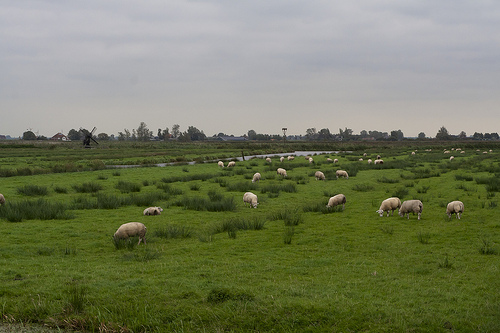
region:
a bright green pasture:
[3, 145, 496, 327]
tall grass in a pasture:
[177, 192, 233, 212]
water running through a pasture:
[101, 144, 358, 173]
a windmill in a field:
[79, 126, 99, 147]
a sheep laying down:
[142, 205, 167, 216]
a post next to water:
[237, 146, 250, 165]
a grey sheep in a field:
[395, 198, 422, 215]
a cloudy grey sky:
[6, 5, 488, 135]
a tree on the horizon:
[436, 126, 448, 138]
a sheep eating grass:
[241, 190, 265, 215]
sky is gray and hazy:
[0, 2, 498, 139]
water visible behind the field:
[108, 147, 340, 165]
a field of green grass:
[1, 145, 498, 331]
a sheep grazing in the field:
[113, 220, 148, 247]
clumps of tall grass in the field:
[211, 216, 266, 236]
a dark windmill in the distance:
[79, 127, 99, 149]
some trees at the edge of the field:
[436, 125, 451, 140]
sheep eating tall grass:
[324, 192, 346, 209]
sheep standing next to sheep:
[376, 195, 401, 218]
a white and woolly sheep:
[240, 191, 260, 210]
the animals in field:
[321, 176, 473, 301]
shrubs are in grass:
[156, 210, 311, 260]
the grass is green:
[225, 240, 462, 319]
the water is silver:
[282, 147, 322, 154]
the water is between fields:
[256, 144, 343, 173]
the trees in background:
[32, 124, 285, 144]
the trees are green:
[66, 122, 219, 139]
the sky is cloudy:
[29, 22, 444, 110]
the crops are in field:
[31, 142, 163, 172]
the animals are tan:
[317, 176, 472, 241]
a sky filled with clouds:
[2, 1, 496, 111]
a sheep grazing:
[102, 214, 160, 249]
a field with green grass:
[280, 252, 464, 330]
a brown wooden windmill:
[74, 121, 106, 153]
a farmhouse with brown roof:
[48, 130, 76, 147]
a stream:
[290, 145, 360, 157]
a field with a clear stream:
[6, 138, 390, 170]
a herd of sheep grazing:
[116, 148, 492, 285]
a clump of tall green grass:
[181, 187, 236, 214]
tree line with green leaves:
[299, 128, 409, 140]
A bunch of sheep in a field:
[83, 134, 491, 279]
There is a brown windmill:
[78, 128, 115, 156]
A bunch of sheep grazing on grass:
[96, 129, 476, 290]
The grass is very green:
[2, 143, 498, 328]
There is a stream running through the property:
[59, 141, 371, 168]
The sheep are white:
[84, 150, 494, 280]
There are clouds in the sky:
[13, 7, 498, 123]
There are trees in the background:
[18, 120, 485, 157]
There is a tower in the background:
[280, 124, 295, 146]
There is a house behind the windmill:
[45, 124, 74, 150]